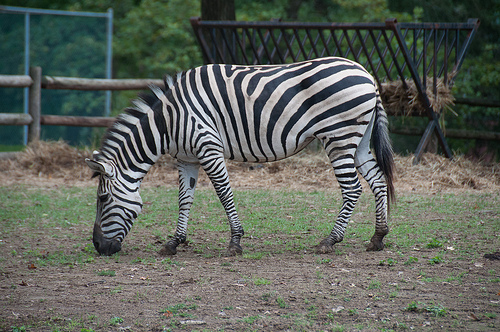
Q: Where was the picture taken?
A: In a zoo.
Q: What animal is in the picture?
A: A zebra.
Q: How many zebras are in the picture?
A: 1.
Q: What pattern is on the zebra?
A: Stripes.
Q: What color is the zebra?
A: Black and white.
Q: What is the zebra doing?
A: Grazing on the grass.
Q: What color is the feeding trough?
A: Black.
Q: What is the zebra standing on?
A: A field of grass with dry patches.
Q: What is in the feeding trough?
A: Hay.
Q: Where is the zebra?
A: The zoo.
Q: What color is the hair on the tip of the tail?
A: Black.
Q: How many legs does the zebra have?
A: Four.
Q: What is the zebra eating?
A: Grass.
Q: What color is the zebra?
A: Black and white.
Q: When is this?
A: Daytime.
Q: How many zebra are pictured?
A: One.